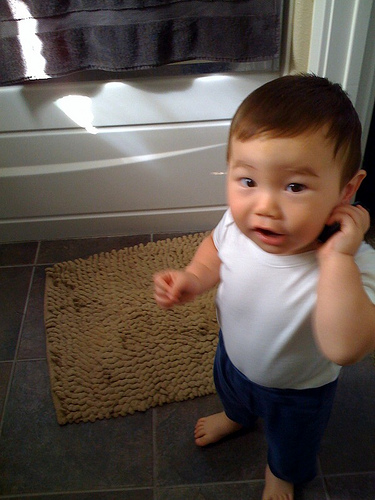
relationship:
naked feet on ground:
[190, 411, 295, 498] [0, 233, 373, 498]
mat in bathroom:
[43, 228, 219, 426] [1, 0, 373, 497]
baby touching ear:
[158, 68, 373, 328] [323, 152, 369, 227]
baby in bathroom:
[151, 68, 375, 500] [1, 0, 373, 497]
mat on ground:
[88, 270, 182, 395] [24, 253, 177, 379]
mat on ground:
[43, 228, 219, 426] [0, 233, 373, 498]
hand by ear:
[330, 202, 371, 249] [329, 160, 368, 253]